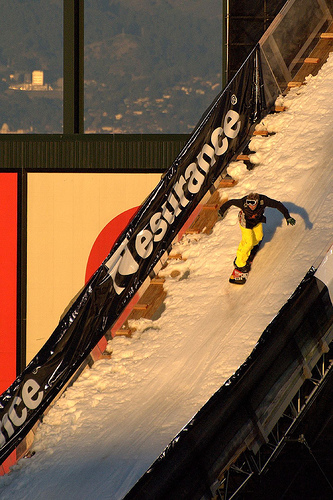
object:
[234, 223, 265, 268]
pants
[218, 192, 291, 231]
jacket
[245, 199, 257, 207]
goggles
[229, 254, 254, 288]
snowboard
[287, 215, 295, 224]
glove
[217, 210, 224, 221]
glove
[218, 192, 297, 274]
man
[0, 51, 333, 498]
snow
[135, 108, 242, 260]
writing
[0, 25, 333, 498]
ramp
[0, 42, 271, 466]
banner